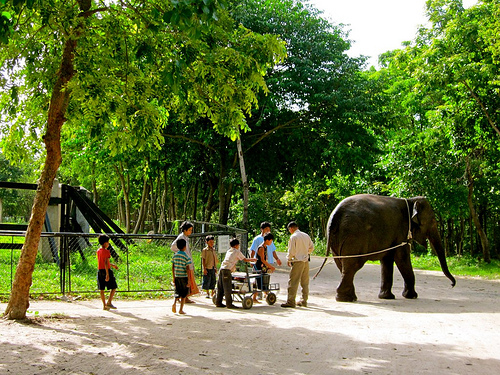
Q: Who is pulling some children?
A: A elephant.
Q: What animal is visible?
A: A elephant.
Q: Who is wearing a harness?
A: A elephant.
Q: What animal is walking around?
A: A elephant.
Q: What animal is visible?
A: A elephant.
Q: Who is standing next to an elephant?
A: A man.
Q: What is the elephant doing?
A: Standing on a road.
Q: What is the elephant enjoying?
A: Some attention.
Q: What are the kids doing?
A: Playing with an elephant.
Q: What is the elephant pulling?
A: A wagon.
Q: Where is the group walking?
A: Behind an elephant.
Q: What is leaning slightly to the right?
A: A tree with bright green leaves.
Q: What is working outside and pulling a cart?
A: An elephant.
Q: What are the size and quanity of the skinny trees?
A: And bunch and tall.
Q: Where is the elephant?
A: In front of a group of people.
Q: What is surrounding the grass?
A: Chain link fence.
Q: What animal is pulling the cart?
A: Elephant.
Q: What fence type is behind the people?
A: Chain link.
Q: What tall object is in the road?
A: Tree.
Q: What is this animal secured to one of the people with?
A: Rope leash.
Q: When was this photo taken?
A: Daytime.